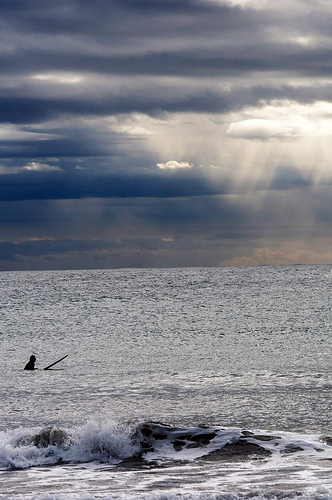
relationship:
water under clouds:
[0, 265, 331, 499] [0, 1, 330, 272]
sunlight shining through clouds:
[1, 1, 331, 271] [0, 1, 330, 272]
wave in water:
[1, 417, 331, 474] [0, 265, 331, 499]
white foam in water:
[0, 418, 331, 500] [0, 265, 331, 499]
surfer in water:
[23, 355, 37, 371] [0, 265, 331, 499]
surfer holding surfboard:
[23, 355, 37, 371] [44, 355, 68, 370]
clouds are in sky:
[0, 1, 330, 272] [1, 1, 331, 271]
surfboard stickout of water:
[44, 355, 68, 370] [0, 265, 331, 499]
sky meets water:
[1, 1, 331, 271] [0, 265, 331, 499]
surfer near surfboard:
[23, 355, 37, 371] [44, 355, 68, 370]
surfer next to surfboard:
[23, 355, 37, 371] [44, 355, 68, 370]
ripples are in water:
[1, 265, 330, 499] [0, 265, 331, 499]